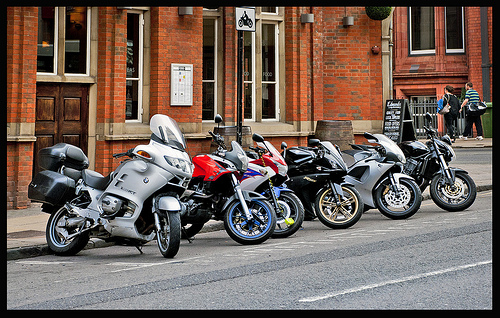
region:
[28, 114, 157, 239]
motorcycle on street side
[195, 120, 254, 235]
motorcycle on street side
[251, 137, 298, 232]
motorcycle on street side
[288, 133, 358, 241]
motorcycle on street side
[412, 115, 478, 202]
motorcycle on street side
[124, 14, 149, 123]
window on side of building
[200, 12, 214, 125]
window on side of building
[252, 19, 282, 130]
window on side of building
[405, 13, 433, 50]
window on side of building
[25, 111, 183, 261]
bike parked on the road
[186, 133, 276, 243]
bike parked on the road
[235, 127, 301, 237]
bike parked on the road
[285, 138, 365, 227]
bike parked on the road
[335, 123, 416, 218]
bike parked on the road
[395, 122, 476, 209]
bike parked on the road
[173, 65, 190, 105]
white sign behind bikes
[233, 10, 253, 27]
white sign of motorcycle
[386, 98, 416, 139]
black sign with white writing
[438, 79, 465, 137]
person walking in distance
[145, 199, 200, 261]
wheel of a bike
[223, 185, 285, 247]
wheel of a bike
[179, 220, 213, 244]
wheel of a bike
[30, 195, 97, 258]
wheel of a bike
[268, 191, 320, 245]
wheel of a bike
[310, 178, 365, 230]
wheel of a bike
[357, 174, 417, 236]
wheel of a bike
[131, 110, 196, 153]
window of a bike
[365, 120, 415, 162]
window of a bike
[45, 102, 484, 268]
a group of bikes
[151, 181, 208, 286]
front tire of bike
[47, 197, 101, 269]
back tire of bike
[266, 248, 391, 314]
a white line in road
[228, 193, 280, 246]
design in the bike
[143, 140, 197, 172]
front light of the bike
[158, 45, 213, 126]
a board in the building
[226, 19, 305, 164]
a window in the building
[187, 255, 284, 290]
a clean road in ground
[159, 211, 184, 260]
a tire on a motorcycle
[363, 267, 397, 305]
white line on the street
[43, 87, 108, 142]
a door to a building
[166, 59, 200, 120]
a sign on the building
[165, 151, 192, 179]
a light on the motorcycle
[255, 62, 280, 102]
window on a building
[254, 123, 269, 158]
a mirror on a motorcycle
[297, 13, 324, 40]
a light on a building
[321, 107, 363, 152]
a barrel outside the building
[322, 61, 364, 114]
brick on a building